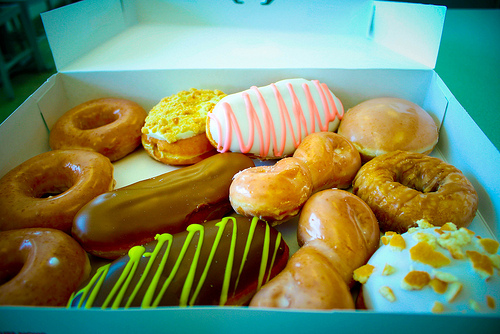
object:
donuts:
[47, 96, 148, 163]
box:
[1, 0, 500, 334]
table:
[433, 6, 500, 151]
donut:
[205, 77, 344, 160]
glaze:
[243, 92, 259, 153]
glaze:
[188, 220, 227, 309]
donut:
[63, 216, 290, 309]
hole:
[73, 111, 119, 130]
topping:
[400, 232, 466, 307]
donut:
[353, 219, 500, 316]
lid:
[37, 0, 448, 73]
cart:
[0, 0, 46, 100]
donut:
[69, 151, 255, 261]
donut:
[0, 149, 117, 237]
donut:
[1, 227, 91, 308]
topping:
[161, 95, 206, 127]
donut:
[139, 86, 229, 166]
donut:
[246, 188, 382, 311]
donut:
[336, 96, 440, 164]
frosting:
[209, 118, 219, 145]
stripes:
[243, 90, 255, 153]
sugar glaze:
[264, 176, 296, 194]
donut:
[228, 132, 362, 226]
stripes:
[218, 217, 240, 307]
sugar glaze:
[367, 104, 415, 137]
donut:
[351, 149, 479, 236]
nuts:
[171, 116, 181, 125]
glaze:
[146, 133, 167, 141]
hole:
[152, 142, 162, 158]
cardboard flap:
[422, 69, 449, 134]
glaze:
[307, 196, 345, 241]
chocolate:
[273, 236, 285, 266]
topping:
[113, 254, 218, 292]